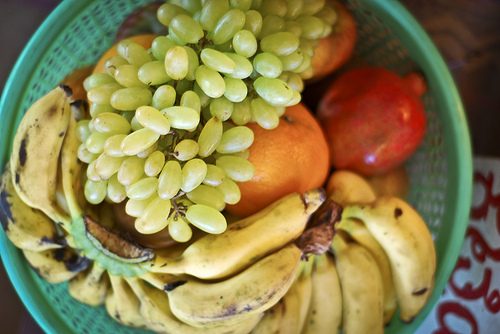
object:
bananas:
[328, 233, 384, 333]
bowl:
[0, 0, 473, 333]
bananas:
[9, 84, 73, 235]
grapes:
[215, 155, 255, 183]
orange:
[302, 0, 358, 84]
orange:
[225, 103, 331, 219]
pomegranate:
[317, 66, 429, 179]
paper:
[413, 157, 499, 333]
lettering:
[431, 169, 499, 334]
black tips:
[59, 84, 73, 97]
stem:
[165, 190, 188, 221]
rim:
[0, 0, 95, 176]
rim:
[363, 0, 474, 334]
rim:
[0, 220, 159, 333]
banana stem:
[69, 212, 157, 277]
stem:
[280, 114, 298, 125]